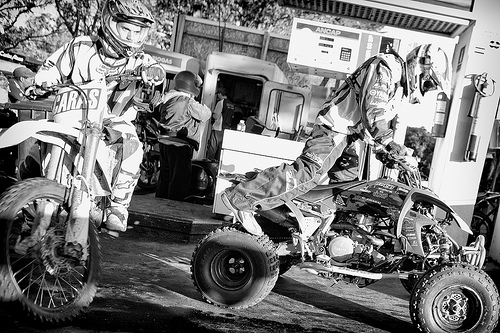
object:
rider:
[215, 38, 455, 237]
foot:
[218, 190, 270, 237]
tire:
[189, 223, 284, 314]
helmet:
[401, 39, 456, 105]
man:
[11, 1, 201, 234]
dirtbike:
[6, 64, 168, 325]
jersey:
[308, 51, 407, 148]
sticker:
[50, 86, 103, 112]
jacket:
[32, 34, 165, 130]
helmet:
[98, 1, 155, 57]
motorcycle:
[183, 126, 499, 333]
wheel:
[1, 176, 105, 327]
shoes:
[98, 201, 132, 234]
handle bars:
[17, 77, 69, 103]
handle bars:
[373, 141, 421, 170]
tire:
[410, 259, 500, 333]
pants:
[222, 125, 363, 214]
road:
[106, 234, 185, 326]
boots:
[102, 180, 134, 233]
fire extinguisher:
[428, 90, 453, 140]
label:
[434, 100, 446, 112]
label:
[433, 112, 446, 126]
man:
[4, 65, 38, 103]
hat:
[12, 65, 38, 78]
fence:
[0, 99, 60, 121]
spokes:
[23, 265, 59, 291]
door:
[256, 79, 314, 138]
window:
[257, 87, 308, 137]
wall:
[423, 0, 500, 192]